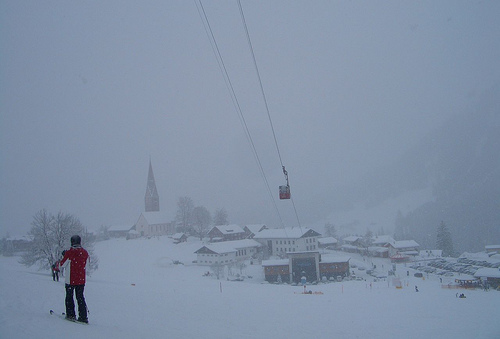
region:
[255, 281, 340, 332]
a ground covered in snow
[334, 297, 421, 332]
ground coverd in white snow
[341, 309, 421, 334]
snow covering the ground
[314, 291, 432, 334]
white snow covering the ground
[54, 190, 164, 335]
a person that is skiing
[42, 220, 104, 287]
a person skiing on the snow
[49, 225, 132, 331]
a person skiing on thew hite snow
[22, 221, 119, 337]
a person on skies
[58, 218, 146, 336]
a person wearing a red jacket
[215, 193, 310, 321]
buildings with snow on roof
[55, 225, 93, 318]
this is a paddy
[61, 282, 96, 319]
these are the legs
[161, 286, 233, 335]
this is the snow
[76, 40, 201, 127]
this is the sky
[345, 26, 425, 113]
the sky is grey in color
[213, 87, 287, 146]
these are two lines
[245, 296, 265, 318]
the snow is white in color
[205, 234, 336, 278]
these are the houses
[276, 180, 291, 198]
this is a carriage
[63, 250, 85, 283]
the jacket is warm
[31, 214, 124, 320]
a mn is on skiingboardd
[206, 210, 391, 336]
buildings are at the background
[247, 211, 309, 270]
buildings are blurred by the snow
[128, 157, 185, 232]
the buildingnis tall in the sky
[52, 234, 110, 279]
the jacket is red in color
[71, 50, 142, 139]
the sky is clear whit in color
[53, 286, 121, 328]
the pants are blavck in color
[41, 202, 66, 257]
the tree is in the middle of the field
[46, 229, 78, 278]
tree is coverd of snow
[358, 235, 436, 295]
the ground id colorfu;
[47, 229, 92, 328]
person wearing skis in snow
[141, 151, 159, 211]
steeple of church in distance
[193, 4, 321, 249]
wires connecting ski lift machines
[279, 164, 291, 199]
square ski lift on wires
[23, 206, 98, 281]
snow-covered tree behind skiier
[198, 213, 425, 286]
small town in distance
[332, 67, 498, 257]
snow-covered mountain in background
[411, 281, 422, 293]
person skiing at bottom of mountain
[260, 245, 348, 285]
building at start of ski lift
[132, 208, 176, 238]
two-story home in front of church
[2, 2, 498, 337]
a scene outside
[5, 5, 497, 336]
a scene during the afternoon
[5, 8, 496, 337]
a scene of a town in the winter time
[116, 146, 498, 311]
a small town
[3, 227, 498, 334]
a skier on a hillside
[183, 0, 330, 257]
a ski lift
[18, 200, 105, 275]
a tree with no leafs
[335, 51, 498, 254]
a hillside in the background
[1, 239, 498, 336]
snow on the ground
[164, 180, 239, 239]
some trees in the distance